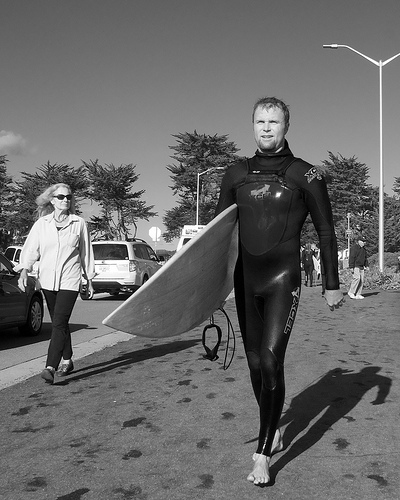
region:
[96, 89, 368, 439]
He is holding a surf board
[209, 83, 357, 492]
He is wearing a wet suit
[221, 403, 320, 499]
He is barefoot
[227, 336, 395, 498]
Man is casting a shadow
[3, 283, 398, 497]
Wet footprints on the ground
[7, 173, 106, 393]
Woman is walking outside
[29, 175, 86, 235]
She is wearing sunglasses on her face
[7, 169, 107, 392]
She is wearing a white jacket and black pants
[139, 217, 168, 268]
There is a stop sign in the distance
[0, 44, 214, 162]
There is only one cloud in the sky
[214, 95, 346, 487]
man in wet suit walking on the pavement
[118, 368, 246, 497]
wet footprints on pavement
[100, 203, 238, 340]
surfboard under man's arm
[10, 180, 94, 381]
woman in button down shirt walking next to man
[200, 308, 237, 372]
ankle strap and rope attached to surfboard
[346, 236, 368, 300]
man in baseball cap walking behind surfboard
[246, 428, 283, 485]
bare feet on pavement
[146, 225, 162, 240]
silver back of octagon shaped sign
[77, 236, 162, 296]
white sport utility vehicles driving on road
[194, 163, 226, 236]
street lamp on post behind surfer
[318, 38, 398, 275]
street light on metal pole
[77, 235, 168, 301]
car on the street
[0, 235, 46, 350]
car on the street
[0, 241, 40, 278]
car on the street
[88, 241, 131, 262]
window of a car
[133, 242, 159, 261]
window of a car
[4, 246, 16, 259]
window of a car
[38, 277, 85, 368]
pair of dark pants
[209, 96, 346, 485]
man wearing a black wetsuit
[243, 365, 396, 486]
shadow behind man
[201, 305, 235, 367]
black leash hanging from surfboard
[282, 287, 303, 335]
white logo printed on wetsuit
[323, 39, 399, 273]
tall metal lamp post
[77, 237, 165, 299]
roof rack on top of white vehicle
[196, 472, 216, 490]
dark spots on top of the pavement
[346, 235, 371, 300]
man standing near lamp post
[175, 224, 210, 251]
van behind surfboard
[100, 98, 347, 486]
man in wetsuit holding surfboard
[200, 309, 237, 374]
strap on a surfboard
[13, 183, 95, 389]
a woman is walking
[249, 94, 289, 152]
the head of a man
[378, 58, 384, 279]
thin metal post for a light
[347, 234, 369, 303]
a man is standing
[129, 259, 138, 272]
tail light on a car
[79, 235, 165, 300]
white suv on the road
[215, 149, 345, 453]
a black wetsuit on a man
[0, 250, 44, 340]
front of a car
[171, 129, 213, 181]
leaves on the tree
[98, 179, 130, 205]
leaves on the tree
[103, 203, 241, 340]
large surfboard being carries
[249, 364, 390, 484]
shadow of the man carrying a surfboard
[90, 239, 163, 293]
white SUV on the road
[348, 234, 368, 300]
person wearing a baseball cap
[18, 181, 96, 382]
woman wearing sunglasses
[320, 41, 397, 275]
tall metal street light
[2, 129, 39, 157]
one small cloud in the sky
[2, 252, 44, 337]
dark colored car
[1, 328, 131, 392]
curb near the road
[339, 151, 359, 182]
green leaves on the tree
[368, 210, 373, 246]
green leaves on the tree